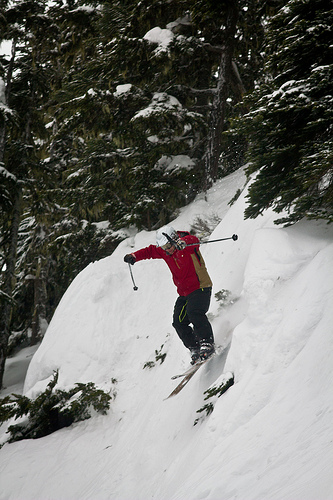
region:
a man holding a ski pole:
[120, 251, 139, 294]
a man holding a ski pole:
[172, 232, 238, 247]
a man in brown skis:
[154, 349, 233, 401]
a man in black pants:
[168, 289, 216, 343]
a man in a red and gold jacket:
[132, 228, 212, 297]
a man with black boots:
[184, 337, 215, 363]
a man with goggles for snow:
[157, 240, 172, 249]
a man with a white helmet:
[152, 225, 176, 246]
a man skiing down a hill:
[113, 226, 240, 398]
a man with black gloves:
[123, 250, 135, 266]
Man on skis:
[162, 325, 237, 404]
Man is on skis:
[163, 324, 236, 402]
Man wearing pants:
[172, 286, 217, 352]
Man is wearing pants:
[171, 284, 219, 351]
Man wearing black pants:
[169, 286, 216, 353]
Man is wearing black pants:
[170, 283, 220, 351]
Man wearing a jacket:
[128, 231, 214, 298]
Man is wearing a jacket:
[128, 235, 214, 299]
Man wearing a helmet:
[152, 223, 181, 247]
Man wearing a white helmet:
[150, 221, 187, 247]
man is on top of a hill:
[128, 215, 231, 371]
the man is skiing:
[126, 215, 235, 380]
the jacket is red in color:
[149, 242, 222, 300]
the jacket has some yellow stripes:
[190, 236, 217, 289]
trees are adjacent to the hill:
[56, 56, 223, 208]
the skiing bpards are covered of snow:
[167, 352, 232, 396]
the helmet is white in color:
[144, 218, 184, 246]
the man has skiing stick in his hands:
[129, 216, 256, 372]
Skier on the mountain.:
[120, 213, 245, 406]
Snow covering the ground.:
[0, 161, 331, 499]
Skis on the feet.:
[163, 344, 225, 404]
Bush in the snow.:
[0, 364, 119, 447]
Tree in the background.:
[0, 0, 330, 385]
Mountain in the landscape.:
[0, 149, 332, 497]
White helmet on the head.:
[150, 219, 179, 258]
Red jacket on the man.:
[118, 220, 215, 298]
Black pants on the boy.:
[122, 216, 232, 359]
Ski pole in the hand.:
[173, 232, 243, 252]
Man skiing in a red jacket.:
[123, 227, 238, 398]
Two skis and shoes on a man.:
[164, 345, 227, 401]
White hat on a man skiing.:
[153, 225, 177, 244]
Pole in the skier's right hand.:
[123, 254, 140, 292]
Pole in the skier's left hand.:
[178, 233, 240, 247]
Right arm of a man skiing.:
[124, 244, 162, 265]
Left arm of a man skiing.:
[174, 234, 200, 252]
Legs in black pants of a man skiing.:
[172, 288, 218, 344]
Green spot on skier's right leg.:
[177, 301, 188, 321]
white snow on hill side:
[251, 277, 292, 320]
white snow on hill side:
[278, 400, 300, 421]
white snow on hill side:
[261, 465, 279, 485]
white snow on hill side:
[284, 433, 303, 455]